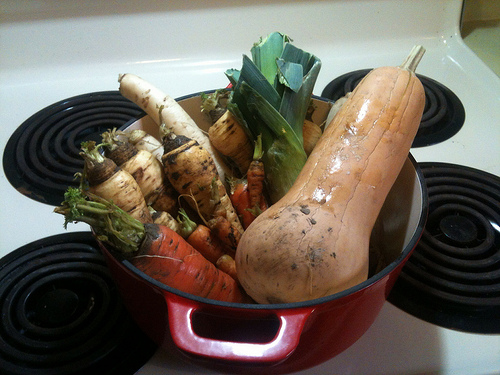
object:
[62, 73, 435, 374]
pot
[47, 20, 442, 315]
vegetable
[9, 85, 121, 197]
stove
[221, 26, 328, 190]
vegetable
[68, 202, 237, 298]
carrot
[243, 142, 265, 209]
carrot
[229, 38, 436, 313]
vegetable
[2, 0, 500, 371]
stove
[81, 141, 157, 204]
parsnip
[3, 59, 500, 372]
4 burners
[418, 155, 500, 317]
burner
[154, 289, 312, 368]
handle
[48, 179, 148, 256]
leaf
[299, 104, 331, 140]
artichoke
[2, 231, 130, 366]
burner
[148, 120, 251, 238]
turnip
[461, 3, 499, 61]
counter